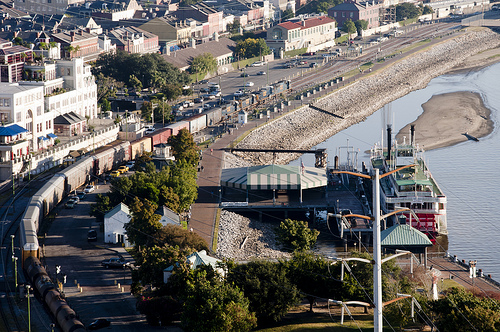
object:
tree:
[282, 252, 360, 320]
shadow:
[252, 311, 375, 327]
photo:
[0, 1, 499, 331]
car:
[254, 70, 265, 79]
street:
[159, 15, 457, 119]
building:
[0, 37, 103, 144]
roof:
[263, 14, 337, 33]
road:
[39, 165, 159, 330]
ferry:
[364, 119, 449, 237]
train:
[217, 77, 291, 117]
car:
[109, 169, 127, 180]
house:
[263, 12, 340, 59]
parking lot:
[44, 242, 143, 322]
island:
[360, 89, 495, 157]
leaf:
[183, 178, 190, 184]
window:
[55, 102, 61, 111]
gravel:
[213, 26, 500, 265]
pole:
[364, 165, 383, 332]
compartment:
[59, 156, 98, 199]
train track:
[288, 18, 470, 87]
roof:
[220, 157, 334, 190]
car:
[97, 255, 127, 272]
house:
[132, 13, 204, 50]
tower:
[24, 285, 32, 300]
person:
[209, 144, 216, 158]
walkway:
[173, 58, 404, 252]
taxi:
[118, 164, 127, 172]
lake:
[283, 60, 498, 285]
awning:
[0, 123, 25, 137]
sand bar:
[228, 25, 499, 169]